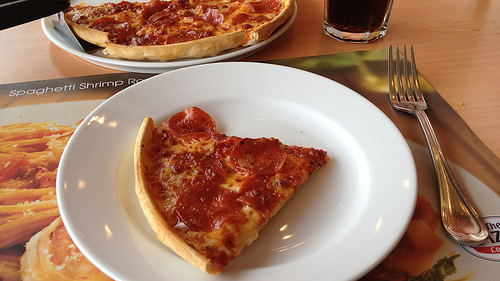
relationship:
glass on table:
[312, 0, 414, 62] [309, 5, 496, 203]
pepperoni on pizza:
[167, 101, 215, 140] [125, 109, 339, 249]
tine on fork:
[377, 33, 412, 102] [380, 37, 489, 261]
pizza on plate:
[125, 109, 339, 249] [45, 55, 444, 279]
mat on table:
[7, 78, 74, 276] [309, 5, 496, 203]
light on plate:
[77, 108, 120, 129] [45, 55, 444, 279]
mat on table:
[0, 47, 500, 281] [309, 5, 496, 203]